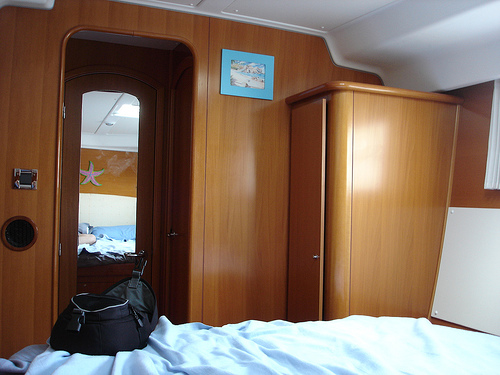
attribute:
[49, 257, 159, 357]
bag — open, black, medium sized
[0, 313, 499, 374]
bed — not spread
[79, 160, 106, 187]
star sign — medium sized, artwork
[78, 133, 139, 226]
wall — wood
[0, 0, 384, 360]
wall — brown wood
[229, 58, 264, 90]
photo — blue, frame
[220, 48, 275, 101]
frame — blue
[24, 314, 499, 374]
bedcover — white, wrinkled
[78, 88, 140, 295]
mirror — middle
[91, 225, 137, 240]
pillow — blue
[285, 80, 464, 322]
closet — brown, wooden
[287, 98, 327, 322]
door — slightly ajar, brown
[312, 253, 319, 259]
knob — silver, small, metal, small silver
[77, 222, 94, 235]
pillow — blue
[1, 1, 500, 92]
ceiling — uneven, white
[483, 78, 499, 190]
curtain — white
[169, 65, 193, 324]
door — wood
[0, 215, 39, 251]
circle — black, speaker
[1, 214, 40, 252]
trim — brown